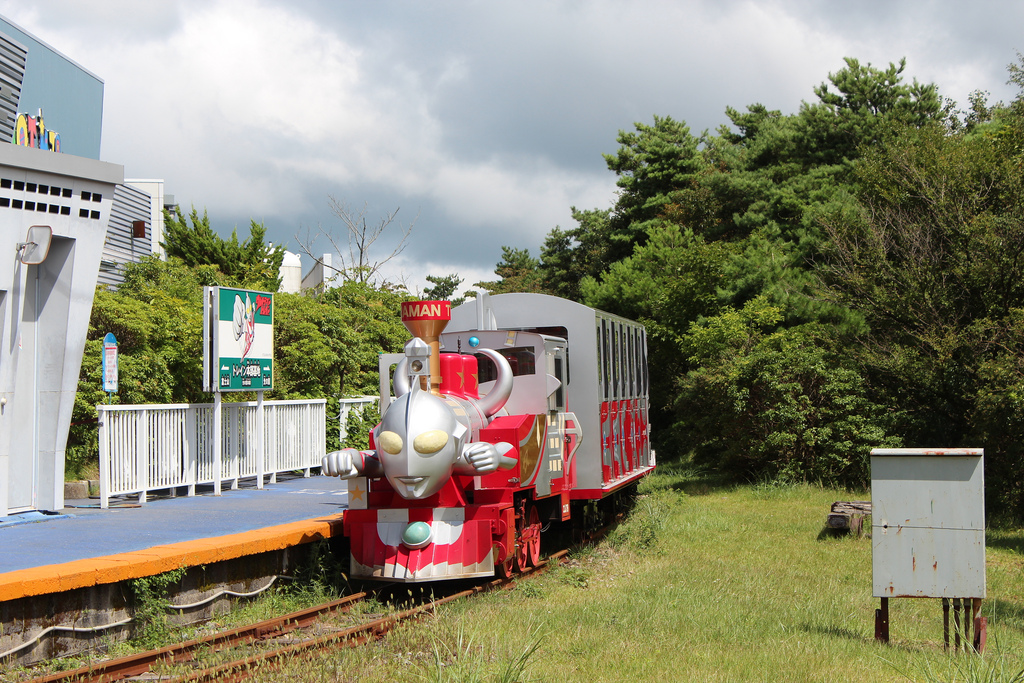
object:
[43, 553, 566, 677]
train tracks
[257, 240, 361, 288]
building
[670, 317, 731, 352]
leaves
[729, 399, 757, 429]
leaves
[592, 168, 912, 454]
tree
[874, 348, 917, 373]
leaves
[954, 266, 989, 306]
leaves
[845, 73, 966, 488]
tree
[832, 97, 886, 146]
leaves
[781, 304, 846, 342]
leaves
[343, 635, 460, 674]
weeds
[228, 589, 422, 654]
train tracks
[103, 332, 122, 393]
sign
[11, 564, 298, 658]
cable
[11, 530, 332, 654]
foundation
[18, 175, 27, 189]
window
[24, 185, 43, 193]
windows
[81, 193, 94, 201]
window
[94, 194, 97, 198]
window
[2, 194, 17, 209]
window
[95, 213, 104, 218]
window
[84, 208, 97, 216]
window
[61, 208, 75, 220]
window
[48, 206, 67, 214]
window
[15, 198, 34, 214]
window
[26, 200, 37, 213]
window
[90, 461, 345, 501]
platform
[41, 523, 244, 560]
line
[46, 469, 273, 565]
platform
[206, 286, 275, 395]
sign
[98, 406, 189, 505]
railing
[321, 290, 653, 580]
train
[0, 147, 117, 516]
building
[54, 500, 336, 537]
platform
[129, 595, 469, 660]
tracks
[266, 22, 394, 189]
cloud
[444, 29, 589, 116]
sky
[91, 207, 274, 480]
trees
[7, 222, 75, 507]
wall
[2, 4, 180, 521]
building